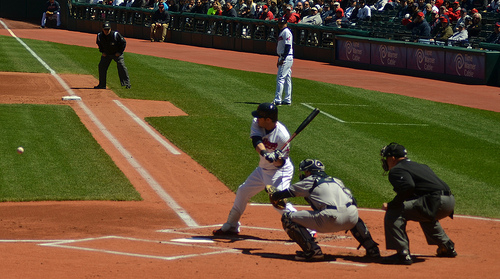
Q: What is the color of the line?
A: White.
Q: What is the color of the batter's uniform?
A: White.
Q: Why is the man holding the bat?
A: To hit the ball.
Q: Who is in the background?
A: Baseball fans.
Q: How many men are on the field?
A: Five.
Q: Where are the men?
A: Baseball field.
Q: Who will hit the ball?
A: The batter.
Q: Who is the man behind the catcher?
A: Umpire.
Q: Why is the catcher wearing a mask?
A: To protect his face.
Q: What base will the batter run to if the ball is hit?
A: First base.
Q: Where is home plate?
A: By the batters right foot.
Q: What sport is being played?
A: Baseball.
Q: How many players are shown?
A: Three.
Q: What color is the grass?
A: Green.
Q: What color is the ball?
A: White.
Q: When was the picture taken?
A: Daytime.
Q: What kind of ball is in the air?
A: A baseball.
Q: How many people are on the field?
A: Five.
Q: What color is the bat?
A: Black and tan.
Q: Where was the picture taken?
A: A baseball diamond.